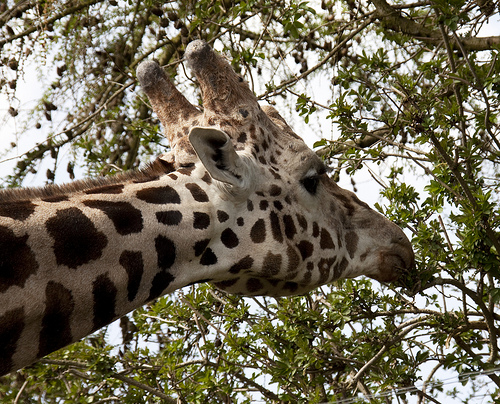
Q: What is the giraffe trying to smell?
A: Leaves.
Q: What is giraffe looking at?
A: Branches of tree.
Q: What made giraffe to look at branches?
A: Hunger.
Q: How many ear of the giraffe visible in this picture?
A: One.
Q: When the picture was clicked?
A: During the Day.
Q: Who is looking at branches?
A: Giraffe.